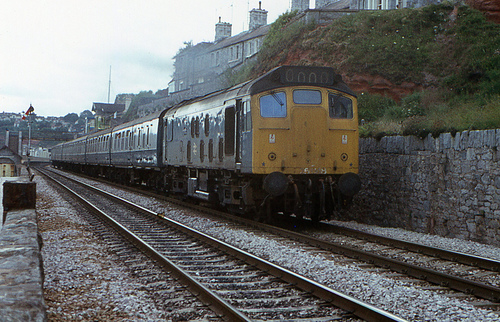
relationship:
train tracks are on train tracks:
[105, 203, 207, 263] [26, 161, 417, 322]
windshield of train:
[253, 89, 285, 124] [163, 70, 361, 200]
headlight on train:
[263, 145, 279, 167] [163, 70, 361, 200]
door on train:
[220, 112, 240, 165] [163, 70, 361, 200]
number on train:
[267, 132, 280, 145] [163, 70, 361, 200]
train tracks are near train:
[105, 203, 207, 263] [163, 70, 361, 200]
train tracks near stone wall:
[105, 203, 207, 263] [404, 136, 464, 178]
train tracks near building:
[105, 203, 207, 263] [214, 40, 249, 62]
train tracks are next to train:
[105, 203, 207, 263] [163, 70, 361, 200]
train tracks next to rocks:
[105, 203, 207, 263] [167, 205, 210, 230]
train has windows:
[163, 70, 361, 200] [253, 83, 357, 125]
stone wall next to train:
[404, 136, 464, 178] [163, 70, 361, 200]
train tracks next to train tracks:
[105, 203, 207, 263] [321, 229, 405, 261]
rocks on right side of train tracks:
[167, 205, 210, 230] [105, 203, 207, 263]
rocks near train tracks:
[167, 205, 210, 230] [105, 203, 207, 263]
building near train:
[214, 40, 249, 62] [163, 70, 361, 200]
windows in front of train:
[253, 83, 357, 125] [163, 70, 361, 200]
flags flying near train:
[19, 97, 40, 119] [163, 70, 361, 200]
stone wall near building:
[404, 136, 464, 178] [214, 40, 249, 62]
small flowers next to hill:
[390, 37, 406, 50] [356, 19, 433, 69]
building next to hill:
[214, 40, 249, 62] [356, 19, 433, 69]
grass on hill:
[452, 41, 486, 86] [356, 19, 433, 69]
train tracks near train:
[105, 203, 207, 263] [163, 70, 361, 200]